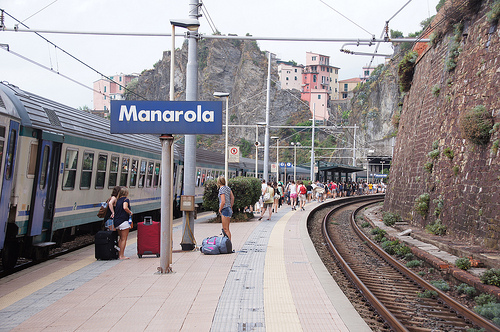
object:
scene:
[0, 3, 499, 331]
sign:
[107, 99, 224, 135]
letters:
[118, 103, 139, 123]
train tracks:
[313, 197, 498, 331]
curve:
[320, 194, 498, 332]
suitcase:
[135, 216, 162, 259]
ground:
[0, 193, 499, 331]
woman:
[214, 175, 234, 254]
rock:
[122, 31, 311, 151]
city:
[0, 0, 499, 331]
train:
[0, 78, 312, 259]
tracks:
[0, 240, 96, 278]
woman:
[113, 187, 133, 259]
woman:
[100, 185, 120, 258]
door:
[30, 140, 58, 236]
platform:
[0, 188, 372, 331]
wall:
[382, 1, 498, 255]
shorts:
[217, 206, 233, 220]